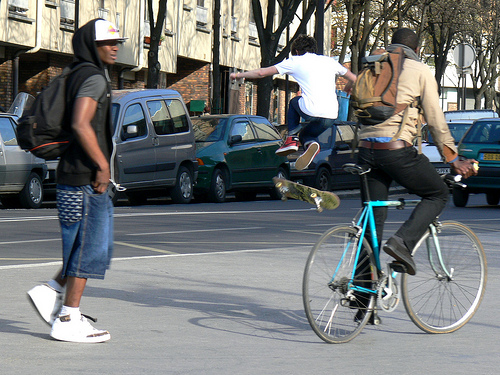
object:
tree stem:
[145, 30, 166, 89]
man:
[230, 34, 359, 169]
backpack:
[346, 47, 408, 126]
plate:
[480, 153, 497, 160]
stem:
[255, 42, 278, 122]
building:
[1, 2, 331, 127]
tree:
[145, 0, 170, 90]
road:
[0, 195, 499, 374]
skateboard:
[270, 172, 342, 214]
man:
[354, 28, 482, 327]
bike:
[297, 161, 487, 343]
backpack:
[13, 60, 106, 160]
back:
[57, 60, 87, 182]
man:
[24, 16, 130, 347]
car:
[451, 117, 500, 211]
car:
[109, 89, 198, 203]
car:
[189, 113, 291, 202]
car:
[0, 111, 46, 208]